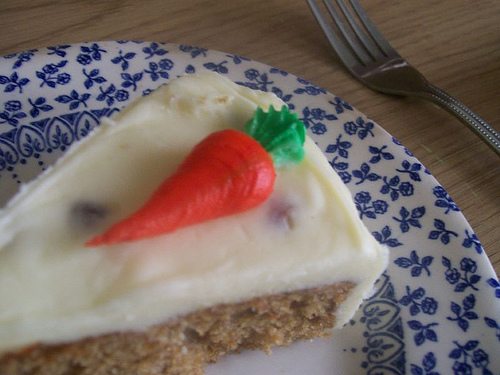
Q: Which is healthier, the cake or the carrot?
A: The carrot is healthier than the cake.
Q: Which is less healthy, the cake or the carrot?
A: The cake is less healthy than the carrot.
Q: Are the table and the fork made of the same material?
A: No, the table is made of wood and the fork is made of metal.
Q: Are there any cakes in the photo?
A: Yes, there is a cake.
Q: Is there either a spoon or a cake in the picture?
A: Yes, there is a cake.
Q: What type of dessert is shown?
A: The dessert is a cake.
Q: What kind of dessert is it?
A: The dessert is a cake.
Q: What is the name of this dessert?
A: That is a cake.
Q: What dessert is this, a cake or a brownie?
A: That is a cake.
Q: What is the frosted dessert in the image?
A: The dessert is a cake.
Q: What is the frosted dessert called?
A: The dessert is a cake.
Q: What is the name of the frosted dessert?
A: The dessert is a cake.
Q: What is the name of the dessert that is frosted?
A: The dessert is a cake.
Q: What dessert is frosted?
A: The dessert is a cake.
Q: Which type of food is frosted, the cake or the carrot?
A: The cake is frosted.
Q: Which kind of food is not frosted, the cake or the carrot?
A: The carrot is not frosted.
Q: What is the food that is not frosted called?
A: The food is a carrot.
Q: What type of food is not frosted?
A: The food is a carrot.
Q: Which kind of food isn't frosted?
A: The food is a carrot.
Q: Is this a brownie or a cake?
A: This is a cake.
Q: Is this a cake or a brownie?
A: This is a cake.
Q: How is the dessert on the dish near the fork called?
A: The dessert is a cake.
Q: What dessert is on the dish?
A: The dessert is a cake.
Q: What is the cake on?
A: The cake is on the dish.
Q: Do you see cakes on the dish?
A: Yes, there is a cake on the dish.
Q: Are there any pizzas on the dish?
A: No, there is a cake on the dish.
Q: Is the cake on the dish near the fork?
A: Yes, the cake is on the dish.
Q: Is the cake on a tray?
A: No, the cake is on the dish.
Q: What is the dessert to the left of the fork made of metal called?
A: The dessert is a cake.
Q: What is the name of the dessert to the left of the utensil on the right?
A: The dessert is a cake.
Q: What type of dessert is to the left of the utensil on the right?
A: The dessert is a cake.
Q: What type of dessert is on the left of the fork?
A: The dessert is a cake.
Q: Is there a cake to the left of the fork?
A: Yes, there is a cake to the left of the fork.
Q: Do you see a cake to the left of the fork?
A: Yes, there is a cake to the left of the fork.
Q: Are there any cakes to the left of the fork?
A: Yes, there is a cake to the left of the fork.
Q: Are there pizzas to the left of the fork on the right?
A: No, there is a cake to the left of the fork.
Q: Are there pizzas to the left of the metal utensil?
A: No, there is a cake to the left of the fork.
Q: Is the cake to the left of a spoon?
A: No, the cake is to the left of the fork.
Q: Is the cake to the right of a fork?
A: No, the cake is to the left of a fork.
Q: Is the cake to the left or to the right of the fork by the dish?
A: The cake is to the left of the fork.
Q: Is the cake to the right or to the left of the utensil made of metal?
A: The cake is to the left of the fork.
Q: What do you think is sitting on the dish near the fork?
A: The cake is sitting on the dish.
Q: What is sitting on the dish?
A: The cake is sitting on the dish.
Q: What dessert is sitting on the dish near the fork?
A: The dessert is a cake.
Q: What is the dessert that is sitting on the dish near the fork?
A: The dessert is a cake.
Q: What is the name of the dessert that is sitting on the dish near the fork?
A: The dessert is a cake.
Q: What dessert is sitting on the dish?
A: The dessert is a cake.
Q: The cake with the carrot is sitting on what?
A: The cake is sitting on the dish.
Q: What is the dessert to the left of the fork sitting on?
A: The cake is sitting on the dish.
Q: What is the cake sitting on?
A: The cake is sitting on the dish.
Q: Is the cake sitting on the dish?
A: Yes, the cake is sitting on the dish.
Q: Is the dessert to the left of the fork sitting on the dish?
A: Yes, the cake is sitting on the dish.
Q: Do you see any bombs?
A: No, there are no bombs.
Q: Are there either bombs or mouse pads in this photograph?
A: No, there are no bombs or mouse pads.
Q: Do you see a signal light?
A: No, there are no traffic lights.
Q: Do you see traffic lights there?
A: No, there are no traffic lights.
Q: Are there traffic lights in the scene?
A: No, there are no traffic lights.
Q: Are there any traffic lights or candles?
A: No, there are no traffic lights or candles.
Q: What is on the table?
A: The dish is on the table.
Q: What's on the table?
A: The dish is on the table.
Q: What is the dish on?
A: The dish is on the table.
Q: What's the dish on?
A: The dish is on the table.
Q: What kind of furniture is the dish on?
A: The dish is on the table.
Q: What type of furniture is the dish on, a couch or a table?
A: The dish is on a table.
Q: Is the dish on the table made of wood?
A: Yes, the dish is on the table.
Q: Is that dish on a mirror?
A: No, the dish is on the table.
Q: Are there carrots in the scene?
A: Yes, there is a carrot.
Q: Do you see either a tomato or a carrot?
A: Yes, there is a carrot.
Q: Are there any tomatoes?
A: No, there are no tomatoes.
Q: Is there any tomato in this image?
A: No, there are no tomatoes.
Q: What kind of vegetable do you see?
A: The vegetable is a carrot.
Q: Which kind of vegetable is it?
A: The vegetable is a carrot.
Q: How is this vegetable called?
A: That is a carrot.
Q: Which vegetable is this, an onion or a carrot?
A: That is a carrot.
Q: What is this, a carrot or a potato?
A: This is a carrot.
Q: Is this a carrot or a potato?
A: This is a carrot.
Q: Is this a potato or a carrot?
A: This is a carrot.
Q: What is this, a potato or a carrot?
A: This is a carrot.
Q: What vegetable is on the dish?
A: The vegetable is a carrot.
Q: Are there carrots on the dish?
A: Yes, there is a carrot on the dish.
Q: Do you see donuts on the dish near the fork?
A: No, there is a carrot on the dish.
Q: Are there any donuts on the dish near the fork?
A: No, there is a carrot on the dish.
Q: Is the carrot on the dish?
A: Yes, the carrot is on the dish.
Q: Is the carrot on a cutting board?
A: No, the carrot is on the dish.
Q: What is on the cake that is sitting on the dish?
A: The carrot is on the cake.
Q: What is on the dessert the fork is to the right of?
A: The carrot is on the cake.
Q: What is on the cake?
A: The carrot is on the cake.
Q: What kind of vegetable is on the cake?
A: The vegetable is a carrot.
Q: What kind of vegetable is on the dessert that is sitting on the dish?
A: The vegetable is a carrot.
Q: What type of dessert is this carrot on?
A: The carrot is on the cake.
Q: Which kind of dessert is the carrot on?
A: The carrot is on the cake.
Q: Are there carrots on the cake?
A: Yes, there is a carrot on the cake.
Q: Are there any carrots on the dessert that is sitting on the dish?
A: Yes, there is a carrot on the cake.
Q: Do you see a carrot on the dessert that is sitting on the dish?
A: Yes, there is a carrot on the cake.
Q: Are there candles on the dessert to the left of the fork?
A: No, there is a carrot on the cake.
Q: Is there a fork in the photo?
A: Yes, there is a fork.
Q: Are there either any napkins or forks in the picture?
A: Yes, there is a fork.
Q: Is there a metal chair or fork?
A: Yes, there is a metal fork.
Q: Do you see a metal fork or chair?
A: Yes, there is a metal fork.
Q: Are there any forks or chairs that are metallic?
A: Yes, the fork is metallic.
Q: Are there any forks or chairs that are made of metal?
A: Yes, the fork is made of metal.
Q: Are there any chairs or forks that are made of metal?
A: Yes, the fork is made of metal.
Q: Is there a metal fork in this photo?
A: Yes, there is a metal fork.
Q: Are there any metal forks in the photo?
A: Yes, there is a metal fork.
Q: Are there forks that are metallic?
A: Yes, there is a fork that is metallic.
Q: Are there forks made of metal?
A: Yes, there is a fork that is made of metal.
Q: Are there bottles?
A: No, there are no bottles.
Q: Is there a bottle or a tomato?
A: No, there are no bottles or tomatoes.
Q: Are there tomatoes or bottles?
A: No, there are no bottles or tomatoes.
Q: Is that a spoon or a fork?
A: That is a fork.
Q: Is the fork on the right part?
A: Yes, the fork is on the right of the image.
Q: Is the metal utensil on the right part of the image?
A: Yes, the fork is on the right of the image.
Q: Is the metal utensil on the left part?
A: No, the fork is on the right of the image.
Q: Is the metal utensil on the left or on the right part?
A: The fork is on the right of the image.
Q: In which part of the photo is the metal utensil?
A: The fork is on the right of the image.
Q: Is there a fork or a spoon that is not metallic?
A: No, there is a fork but it is metallic.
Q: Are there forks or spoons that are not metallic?
A: No, there is a fork but it is metallic.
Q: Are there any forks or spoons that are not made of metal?
A: No, there is a fork but it is made of metal.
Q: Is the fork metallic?
A: Yes, the fork is metallic.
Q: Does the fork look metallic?
A: Yes, the fork is metallic.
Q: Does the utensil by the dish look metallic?
A: Yes, the fork is metallic.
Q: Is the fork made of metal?
A: Yes, the fork is made of metal.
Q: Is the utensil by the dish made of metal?
A: Yes, the fork is made of metal.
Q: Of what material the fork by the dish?
A: The fork is made of metal.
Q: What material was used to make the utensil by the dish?
A: The fork is made of metal.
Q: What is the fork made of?
A: The fork is made of metal.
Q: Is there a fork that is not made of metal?
A: No, there is a fork but it is made of metal.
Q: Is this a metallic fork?
A: Yes, this is a metallic fork.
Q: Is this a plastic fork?
A: No, this is a metallic fork.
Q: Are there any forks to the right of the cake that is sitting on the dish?
A: Yes, there is a fork to the right of the cake.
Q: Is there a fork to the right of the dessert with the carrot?
A: Yes, there is a fork to the right of the cake.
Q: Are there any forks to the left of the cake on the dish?
A: No, the fork is to the right of the cake.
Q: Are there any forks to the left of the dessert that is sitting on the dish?
A: No, the fork is to the right of the cake.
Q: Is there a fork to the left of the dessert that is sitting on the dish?
A: No, the fork is to the right of the cake.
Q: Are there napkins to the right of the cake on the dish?
A: No, there is a fork to the right of the cake.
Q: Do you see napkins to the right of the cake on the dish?
A: No, there is a fork to the right of the cake.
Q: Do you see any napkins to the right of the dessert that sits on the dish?
A: No, there is a fork to the right of the cake.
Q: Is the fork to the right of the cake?
A: Yes, the fork is to the right of the cake.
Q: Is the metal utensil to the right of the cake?
A: Yes, the fork is to the right of the cake.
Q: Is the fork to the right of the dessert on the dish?
A: Yes, the fork is to the right of the cake.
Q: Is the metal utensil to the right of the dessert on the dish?
A: Yes, the fork is to the right of the cake.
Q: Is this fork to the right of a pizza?
A: No, the fork is to the right of the cake.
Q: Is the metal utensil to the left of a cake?
A: No, the fork is to the right of a cake.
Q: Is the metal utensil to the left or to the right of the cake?
A: The fork is to the right of the cake.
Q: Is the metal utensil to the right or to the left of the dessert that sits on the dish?
A: The fork is to the right of the cake.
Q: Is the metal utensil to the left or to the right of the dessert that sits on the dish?
A: The fork is to the right of the cake.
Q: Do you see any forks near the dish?
A: Yes, there is a fork near the dish.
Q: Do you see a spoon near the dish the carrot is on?
A: No, there is a fork near the dish.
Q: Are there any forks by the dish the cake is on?
A: Yes, there is a fork by the dish.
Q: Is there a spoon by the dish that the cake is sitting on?
A: No, there is a fork by the dish.